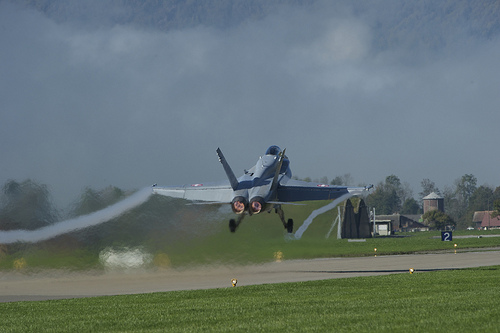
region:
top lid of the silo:
[425, 187, 445, 203]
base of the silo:
[427, 198, 449, 227]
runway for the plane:
[309, 258, 452, 281]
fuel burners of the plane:
[227, 193, 284, 224]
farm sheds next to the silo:
[370, 201, 442, 239]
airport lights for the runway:
[373, 253, 427, 281]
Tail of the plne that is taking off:
[209, 142, 254, 187]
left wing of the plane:
[153, 179, 236, 209]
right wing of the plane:
[273, 170, 378, 203]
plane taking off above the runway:
[166, 125, 366, 228]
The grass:
[322, 281, 380, 329]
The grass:
[322, 265, 432, 325]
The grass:
[395, 275, 473, 329]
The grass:
[348, 295, 392, 330]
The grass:
[351, 307, 375, 327]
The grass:
[350, 268, 395, 322]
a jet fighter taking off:
[35, 16, 485, 295]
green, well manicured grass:
[342, 279, 447, 326]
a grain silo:
[415, 177, 463, 237]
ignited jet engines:
[230, 191, 276, 219]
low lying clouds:
[125, 20, 441, 140]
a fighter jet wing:
[302, 160, 404, 255]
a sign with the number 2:
[427, 220, 472, 257]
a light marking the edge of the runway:
[221, 263, 253, 303]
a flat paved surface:
[312, 263, 421, 283]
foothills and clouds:
[78, 3, 495, 160]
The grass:
[313, 279, 323, 289]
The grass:
[363, 301, 371, 306]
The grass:
[371, 276, 412, 317]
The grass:
[359, 289, 410, 327]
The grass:
[376, 305, 399, 331]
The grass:
[336, 309, 371, 329]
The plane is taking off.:
[125, 145, 368, 274]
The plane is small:
[101, 118, 372, 273]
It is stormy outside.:
[36, 13, 486, 142]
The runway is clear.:
[51, 257, 497, 291]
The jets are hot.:
[199, 196, 296, 258]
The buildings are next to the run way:
[323, 175, 499, 246]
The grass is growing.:
[120, 278, 493, 330]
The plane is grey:
[101, 118, 396, 220]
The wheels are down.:
[203, 190, 340, 252]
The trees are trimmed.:
[328, 189, 394, 260]